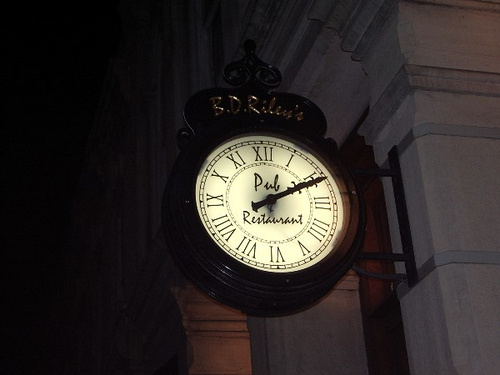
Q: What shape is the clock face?
A: Round.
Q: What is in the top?
A: Clock.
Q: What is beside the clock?
A: Wall.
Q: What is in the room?
A: Clock.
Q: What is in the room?
A: Pillar.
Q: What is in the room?
A: Clock.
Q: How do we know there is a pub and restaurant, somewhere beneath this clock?
A: The clock face has the words Pub and Restaurant.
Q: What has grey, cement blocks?
A: A building, with a clock attached to it.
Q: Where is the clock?
A: Mounted to the side of a bullding.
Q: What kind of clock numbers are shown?
A: Roman Numerals.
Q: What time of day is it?
A: It is 2:11, in the morning.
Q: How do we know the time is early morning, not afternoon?
A: The sky is black.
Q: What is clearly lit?
A: The clockface.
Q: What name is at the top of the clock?
A: B.D. Riley.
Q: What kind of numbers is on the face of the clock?
A: Roman numerals.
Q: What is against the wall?
A: Door.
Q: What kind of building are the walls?
A: Gray stone.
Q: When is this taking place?
A: Night time.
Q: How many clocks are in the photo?
A: One.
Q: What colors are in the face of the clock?
A: White and black.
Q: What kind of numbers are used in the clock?
A: Roman numerals.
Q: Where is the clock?
A: On the side of the building.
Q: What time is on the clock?
A: 2:10.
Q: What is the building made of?
A: Stone.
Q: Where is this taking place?
A: Outside during the night time.